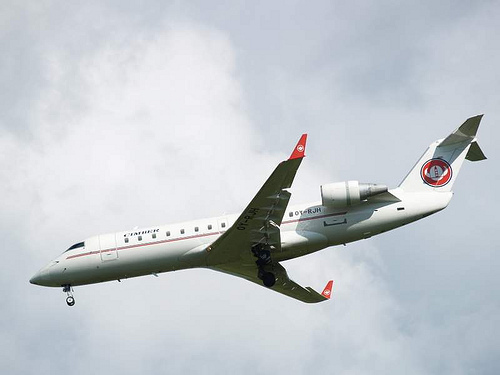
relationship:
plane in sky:
[64, 114, 474, 311] [205, 17, 353, 77]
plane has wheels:
[64, 114, 474, 311] [250, 246, 288, 295]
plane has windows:
[64, 114, 474, 311] [180, 224, 212, 238]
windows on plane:
[180, 224, 212, 238] [64, 114, 474, 311]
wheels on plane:
[250, 246, 288, 295] [64, 114, 474, 311]